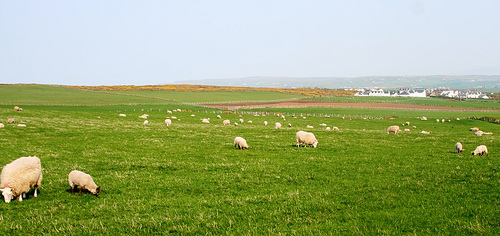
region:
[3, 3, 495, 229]
sheep grazing on pasture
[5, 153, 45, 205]
large tan sheep with white face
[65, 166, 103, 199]
small tan sheep with black face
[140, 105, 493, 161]
a large flock of sheep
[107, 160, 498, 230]
patch of green grass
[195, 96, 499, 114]
reddish brown soil by pasture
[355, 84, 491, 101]
buildings by the pasture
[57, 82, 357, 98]
patch of yellow grass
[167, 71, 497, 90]
mountains behind the buildings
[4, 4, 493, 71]
hazy blue sky over pasture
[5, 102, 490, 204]
Sheep in the field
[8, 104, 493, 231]
The field has green grass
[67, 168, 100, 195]
A small sheep in the field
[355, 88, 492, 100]
Buildings beyond the sheep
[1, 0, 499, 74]
Blue sky above the sheep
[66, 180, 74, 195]
The back legs of the sheep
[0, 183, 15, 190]
The ears of the sheep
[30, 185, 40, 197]
The back leg of a sheep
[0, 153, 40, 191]
The sheep has white fur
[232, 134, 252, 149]
The small sheep is eating grass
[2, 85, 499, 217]
sheeps in a field of green grass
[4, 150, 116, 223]
two sheeps eating grass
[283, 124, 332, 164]
a sheep eats grass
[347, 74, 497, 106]
homes in front a green field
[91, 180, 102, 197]
head of sheep is black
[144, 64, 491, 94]
mountains in the background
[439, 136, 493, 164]
two sheeps eating grass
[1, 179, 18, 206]
head of sheep is white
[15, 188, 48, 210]
legs of sheep are white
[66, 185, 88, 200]
legs of sheep are black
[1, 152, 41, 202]
a sheep in a field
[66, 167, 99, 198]
a small sheep in a field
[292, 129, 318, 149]
a sheep in a field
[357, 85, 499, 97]
water crashing to the shore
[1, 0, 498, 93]
the sky, horizon, and water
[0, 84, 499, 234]
grassy hills filled with sheep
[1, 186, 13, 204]
head of a sheep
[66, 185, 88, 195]
shadow of a small sheep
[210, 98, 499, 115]
a road in the distance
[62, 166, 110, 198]
a small, baby sheep grazing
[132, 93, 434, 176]
flock of sheep grazing in a field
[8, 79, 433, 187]
soft rolling green hills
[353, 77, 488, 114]
dwellings in a local town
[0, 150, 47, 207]
large sheep eating some grass in a field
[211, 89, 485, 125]
tilled land ready for planting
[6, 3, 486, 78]
clear, blue skies on a sunny day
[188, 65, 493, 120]
rolling hills in the distance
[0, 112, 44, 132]
sheep from a flock lying down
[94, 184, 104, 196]
a small lamb with a black head